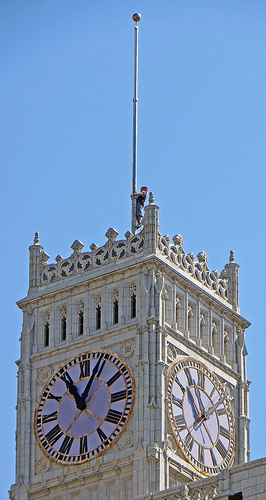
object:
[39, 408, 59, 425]
roman numeral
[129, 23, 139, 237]
pole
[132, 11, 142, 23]
ball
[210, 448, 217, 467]
numerals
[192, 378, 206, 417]
hands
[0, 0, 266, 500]
sky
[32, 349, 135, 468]
clock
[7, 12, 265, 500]
building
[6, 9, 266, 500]
tower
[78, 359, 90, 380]
numeral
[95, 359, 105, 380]
numeral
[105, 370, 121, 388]
numeral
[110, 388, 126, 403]
numeral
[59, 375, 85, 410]
hands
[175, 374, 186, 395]
numbers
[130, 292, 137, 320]
window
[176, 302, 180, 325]
window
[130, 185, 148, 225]
person